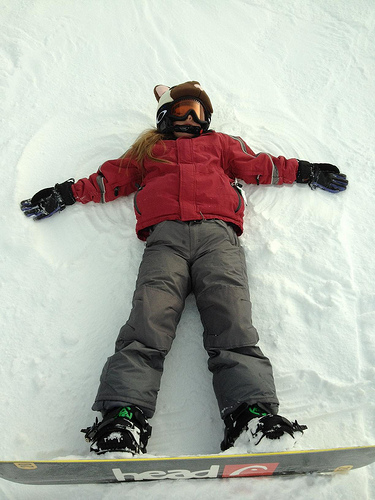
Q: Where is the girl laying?
A: In the snow.